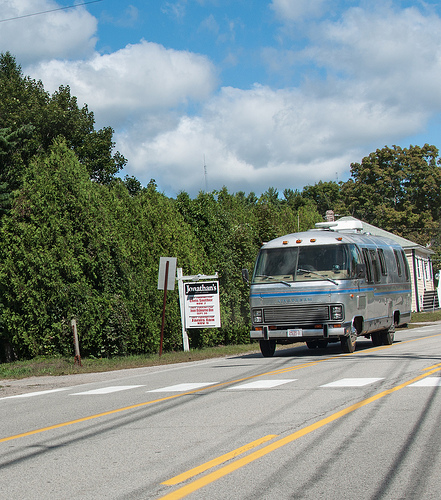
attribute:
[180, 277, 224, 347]
sign — local advertising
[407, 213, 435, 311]
building — small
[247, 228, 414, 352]
van — silver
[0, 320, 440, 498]
street — paved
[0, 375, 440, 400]
crosswalk — white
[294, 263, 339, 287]
wiper — windshield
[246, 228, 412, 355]
vehicle — silver, recreational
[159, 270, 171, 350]
post — wooden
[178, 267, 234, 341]
sign — METAL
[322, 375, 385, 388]
box — white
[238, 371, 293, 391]
box — white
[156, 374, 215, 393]
box — white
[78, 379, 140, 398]
box — white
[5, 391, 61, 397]
box — white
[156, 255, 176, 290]
sign — street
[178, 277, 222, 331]
sign — white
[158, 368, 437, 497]
line — long, yellow, painted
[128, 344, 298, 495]
road — paved 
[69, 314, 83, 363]
pole — metal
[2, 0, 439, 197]
sky — blue, cloudy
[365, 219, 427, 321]
house — distant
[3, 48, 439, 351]
foliage — green